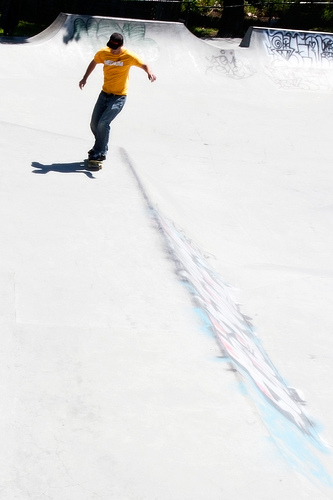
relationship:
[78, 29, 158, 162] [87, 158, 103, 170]
he riding skateboard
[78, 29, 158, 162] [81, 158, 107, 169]
he on skateboard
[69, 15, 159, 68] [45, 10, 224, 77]
green design on ramp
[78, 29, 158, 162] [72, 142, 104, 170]
he riding skateboard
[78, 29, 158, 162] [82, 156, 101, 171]
he on skateboard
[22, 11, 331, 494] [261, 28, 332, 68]
ramp has graffiti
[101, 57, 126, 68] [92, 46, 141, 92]
logo on shirt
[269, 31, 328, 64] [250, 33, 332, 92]
design on wall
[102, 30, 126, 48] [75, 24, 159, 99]
hat on man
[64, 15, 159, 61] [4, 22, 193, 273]
green design on left wall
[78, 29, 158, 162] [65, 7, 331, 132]
he in skatepark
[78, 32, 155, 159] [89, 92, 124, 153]
he wearing blue jeans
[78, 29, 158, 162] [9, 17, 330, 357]
he in skate park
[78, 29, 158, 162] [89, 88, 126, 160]
he wearing blue jeans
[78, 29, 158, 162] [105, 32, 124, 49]
he wearing hat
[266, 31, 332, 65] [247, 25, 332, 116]
design on ramp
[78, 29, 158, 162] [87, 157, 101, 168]
he on skateboard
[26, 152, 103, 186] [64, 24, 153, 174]
shadow of man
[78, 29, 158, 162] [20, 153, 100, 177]
he cassting shadow